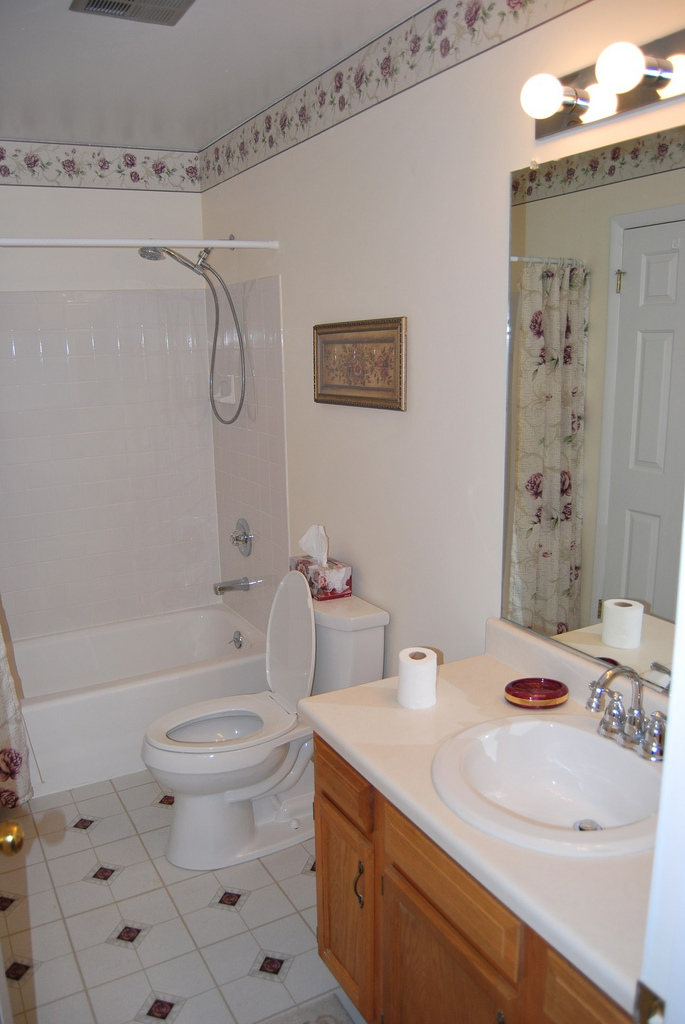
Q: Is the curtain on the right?
A: Yes, the curtain is on the right of the image.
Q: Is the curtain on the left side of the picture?
A: No, the curtain is on the right of the image.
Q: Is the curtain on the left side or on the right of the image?
A: The curtain is on the right of the image.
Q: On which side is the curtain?
A: The curtain is on the right of the image.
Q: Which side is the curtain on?
A: The curtain is on the right of the image.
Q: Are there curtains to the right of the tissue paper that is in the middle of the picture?
A: Yes, there is a curtain to the right of the tissue paper.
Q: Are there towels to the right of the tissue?
A: No, there is a curtain to the right of the tissue.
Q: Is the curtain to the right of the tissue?
A: Yes, the curtain is to the right of the tissue.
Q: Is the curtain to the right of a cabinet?
A: No, the curtain is to the right of the tissue.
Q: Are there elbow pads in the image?
A: No, there are no elbow pads.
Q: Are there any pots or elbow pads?
A: No, there are no elbow pads or pots.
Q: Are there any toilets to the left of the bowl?
A: Yes, there is a toilet to the left of the bowl.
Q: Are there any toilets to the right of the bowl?
A: No, the toilet is to the left of the bowl.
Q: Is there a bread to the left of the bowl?
A: No, there is a toilet to the left of the bowl.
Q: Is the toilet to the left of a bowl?
A: Yes, the toilet is to the left of a bowl.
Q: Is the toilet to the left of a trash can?
A: No, the toilet is to the left of a bowl.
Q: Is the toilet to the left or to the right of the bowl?
A: The toilet is to the left of the bowl.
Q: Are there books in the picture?
A: No, there are no books.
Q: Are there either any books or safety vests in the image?
A: No, there are no books or safety vests.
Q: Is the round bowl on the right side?
A: Yes, the bowl is on the right of the image.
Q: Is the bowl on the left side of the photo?
A: No, the bowl is on the right of the image.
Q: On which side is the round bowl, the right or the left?
A: The bowl is on the right of the image.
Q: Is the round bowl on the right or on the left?
A: The bowl is on the right of the image.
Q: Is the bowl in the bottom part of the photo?
A: Yes, the bowl is in the bottom of the image.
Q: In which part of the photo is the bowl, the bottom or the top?
A: The bowl is in the bottom of the image.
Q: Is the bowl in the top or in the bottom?
A: The bowl is in the bottom of the image.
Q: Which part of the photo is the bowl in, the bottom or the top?
A: The bowl is in the bottom of the image.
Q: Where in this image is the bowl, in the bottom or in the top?
A: The bowl is in the bottom of the image.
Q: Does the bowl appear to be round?
A: Yes, the bowl is round.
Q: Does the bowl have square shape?
A: No, the bowl is round.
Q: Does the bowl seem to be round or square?
A: The bowl is round.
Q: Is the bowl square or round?
A: The bowl is round.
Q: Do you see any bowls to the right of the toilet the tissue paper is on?
A: Yes, there is a bowl to the right of the toilet.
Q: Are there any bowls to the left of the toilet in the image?
A: No, the bowl is to the right of the toilet.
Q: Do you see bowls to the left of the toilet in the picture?
A: No, the bowl is to the right of the toilet.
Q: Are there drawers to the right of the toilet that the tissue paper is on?
A: No, there is a bowl to the right of the toilet.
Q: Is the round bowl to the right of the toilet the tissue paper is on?
A: Yes, the bowl is to the right of the toilet.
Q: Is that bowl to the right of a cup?
A: No, the bowl is to the right of the toilet.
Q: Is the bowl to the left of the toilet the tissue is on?
A: No, the bowl is to the right of the toilet.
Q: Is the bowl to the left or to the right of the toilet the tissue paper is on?
A: The bowl is to the right of the toilet.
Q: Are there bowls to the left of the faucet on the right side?
A: Yes, there is a bowl to the left of the faucet.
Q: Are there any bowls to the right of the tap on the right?
A: No, the bowl is to the left of the tap.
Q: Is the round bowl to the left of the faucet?
A: Yes, the bowl is to the left of the faucet.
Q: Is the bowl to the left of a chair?
A: No, the bowl is to the left of the faucet.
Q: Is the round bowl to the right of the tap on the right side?
A: No, the bowl is to the left of the faucet.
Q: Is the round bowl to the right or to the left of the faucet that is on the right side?
A: The bowl is to the left of the faucet.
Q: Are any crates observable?
A: No, there are no crates.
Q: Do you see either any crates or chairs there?
A: No, there are no crates or chairs.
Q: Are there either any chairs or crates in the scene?
A: No, there are no crates or chairs.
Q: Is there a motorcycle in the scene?
A: No, there are no motorcycles.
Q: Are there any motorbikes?
A: No, there are no motorbikes.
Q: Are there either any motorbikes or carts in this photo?
A: No, there are no motorbikes or carts.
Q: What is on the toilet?
A: The tissue paper is on the toilet.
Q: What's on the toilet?
A: The tissue paper is on the toilet.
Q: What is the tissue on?
A: The tissue is on the toilet.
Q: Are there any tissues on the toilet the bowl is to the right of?
A: Yes, there is a tissue on the toilet.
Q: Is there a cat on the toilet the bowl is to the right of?
A: No, there is a tissue on the toilet.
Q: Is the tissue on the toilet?
A: Yes, the tissue is on the toilet.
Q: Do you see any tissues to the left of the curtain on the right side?
A: Yes, there is a tissue to the left of the curtain.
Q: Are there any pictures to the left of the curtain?
A: No, there is a tissue to the left of the curtain.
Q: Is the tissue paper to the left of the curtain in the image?
A: Yes, the tissue paper is to the left of the curtain.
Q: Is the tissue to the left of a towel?
A: No, the tissue is to the left of the curtain.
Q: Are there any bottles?
A: No, there are no bottles.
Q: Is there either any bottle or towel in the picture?
A: No, there are no bottles or towels.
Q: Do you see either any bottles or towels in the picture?
A: No, there are no bottles or towels.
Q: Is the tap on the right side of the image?
A: Yes, the tap is on the right of the image.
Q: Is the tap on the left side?
A: No, the tap is on the right of the image.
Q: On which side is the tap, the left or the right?
A: The tap is on the right of the image.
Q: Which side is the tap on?
A: The tap is on the right of the image.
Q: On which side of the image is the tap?
A: The tap is on the right of the image.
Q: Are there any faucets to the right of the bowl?
A: Yes, there is a faucet to the right of the bowl.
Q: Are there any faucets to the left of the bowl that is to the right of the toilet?
A: No, the faucet is to the right of the bowl.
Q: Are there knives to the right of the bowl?
A: No, there is a faucet to the right of the bowl.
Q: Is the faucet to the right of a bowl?
A: Yes, the faucet is to the right of a bowl.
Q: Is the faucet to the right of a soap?
A: No, the faucet is to the right of a bowl.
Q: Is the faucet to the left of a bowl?
A: No, the faucet is to the right of a bowl.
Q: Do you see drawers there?
A: No, there are no drawers.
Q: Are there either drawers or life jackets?
A: No, there are no drawers or life jackets.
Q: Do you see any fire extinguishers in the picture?
A: No, there are no fire extinguishers.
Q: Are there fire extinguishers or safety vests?
A: No, there are no fire extinguishers or safety vests.